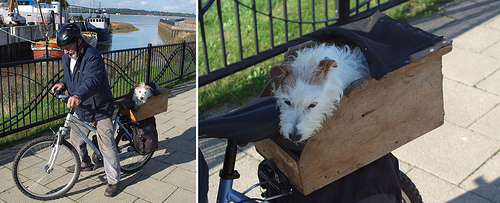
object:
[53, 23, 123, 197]
man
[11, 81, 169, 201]
bike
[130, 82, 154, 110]
dog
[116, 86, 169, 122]
box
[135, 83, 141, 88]
ears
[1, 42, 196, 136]
railings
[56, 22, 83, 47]
helmet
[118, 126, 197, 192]
shadow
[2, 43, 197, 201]
ground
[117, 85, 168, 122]
wood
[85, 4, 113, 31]
boats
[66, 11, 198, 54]
ocean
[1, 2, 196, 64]
background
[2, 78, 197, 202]
sidewalk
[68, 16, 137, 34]
inlet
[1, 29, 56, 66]
wall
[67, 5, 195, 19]
shore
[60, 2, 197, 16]
distance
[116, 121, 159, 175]
tire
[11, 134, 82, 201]
tire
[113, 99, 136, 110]
seat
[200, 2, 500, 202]
walkway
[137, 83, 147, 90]
hair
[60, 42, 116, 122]
jacket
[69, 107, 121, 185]
pants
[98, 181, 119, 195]
shoes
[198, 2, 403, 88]
fence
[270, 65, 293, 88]
brown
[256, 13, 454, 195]
basket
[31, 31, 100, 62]
boat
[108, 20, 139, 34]
land